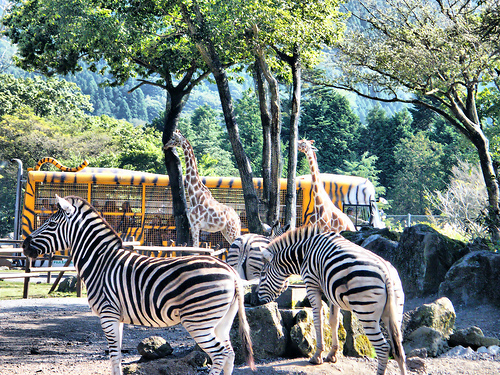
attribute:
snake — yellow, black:
[24, 156, 93, 170]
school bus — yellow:
[15, 173, 360, 235]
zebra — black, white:
[8, 207, 236, 370]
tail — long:
[219, 284, 259, 367]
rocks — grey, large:
[240, 303, 299, 354]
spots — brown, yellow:
[313, 215, 347, 229]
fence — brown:
[29, 260, 88, 295]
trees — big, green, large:
[60, 122, 155, 163]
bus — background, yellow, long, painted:
[195, 174, 378, 217]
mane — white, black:
[84, 206, 133, 240]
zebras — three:
[19, 238, 340, 348]